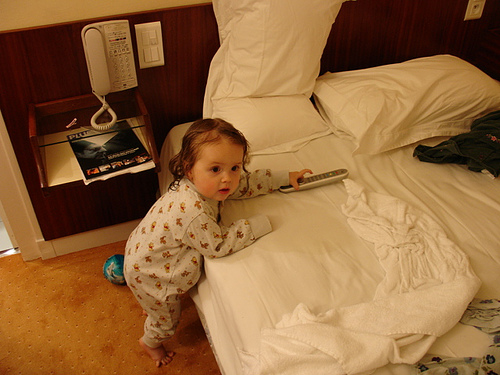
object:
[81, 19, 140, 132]
phone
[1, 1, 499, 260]
wall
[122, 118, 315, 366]
girl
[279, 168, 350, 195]
remote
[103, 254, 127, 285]
ball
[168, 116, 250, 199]
hair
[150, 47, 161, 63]
light switches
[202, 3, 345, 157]
pillow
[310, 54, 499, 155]
pillow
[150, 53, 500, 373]
bed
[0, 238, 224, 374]
carpet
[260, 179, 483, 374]
towel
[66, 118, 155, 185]
magazine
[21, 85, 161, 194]
shelf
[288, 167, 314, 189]
hand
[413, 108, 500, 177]
clothing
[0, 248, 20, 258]
floor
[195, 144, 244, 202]
face